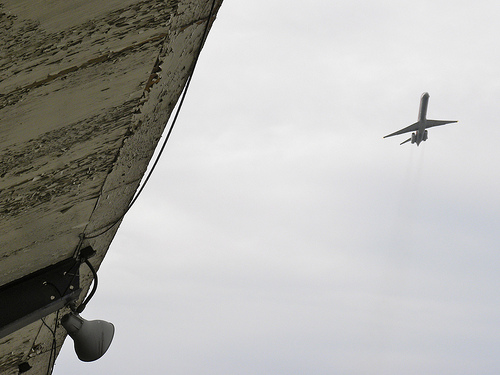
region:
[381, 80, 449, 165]
plane in flight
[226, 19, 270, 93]
white clouds against blue sky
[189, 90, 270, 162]
white clouds against blue sky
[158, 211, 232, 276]
white clouds against blue sky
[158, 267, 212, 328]
white clouds against blue sky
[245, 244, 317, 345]
white clouds against blue sky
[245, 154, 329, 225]
white clouds against blue sky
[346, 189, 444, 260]
white clouds against blue sky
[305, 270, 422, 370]
white clouds against blue sky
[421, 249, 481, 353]
white clouds against blue sky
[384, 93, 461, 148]
The plane flying vertically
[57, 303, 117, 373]
The gray lighting on the wall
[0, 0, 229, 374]
The old gray paint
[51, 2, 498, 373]
The gray open sky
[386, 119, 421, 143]
The gray wing on the left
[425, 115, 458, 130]
The gray wing on the right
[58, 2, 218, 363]
The black cable on the wall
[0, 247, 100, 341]
The dark roofing bar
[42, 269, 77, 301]
The bar with four holes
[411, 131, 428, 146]
The rear plane engines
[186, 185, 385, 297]
Sky is white color.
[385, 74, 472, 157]
Plane is flying in air.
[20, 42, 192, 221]
part of boat is seen in let side.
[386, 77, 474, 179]
plane is white color.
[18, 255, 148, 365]
light is attached to the boat.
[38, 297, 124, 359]
Light is white color.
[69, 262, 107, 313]
Wire is black color.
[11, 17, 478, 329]
Day time picture.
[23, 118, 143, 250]
Boat is grey color.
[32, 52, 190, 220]
boat is made of wood.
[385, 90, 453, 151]
The jet is in the air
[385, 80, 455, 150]
The jet is white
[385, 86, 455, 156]
The jet is flying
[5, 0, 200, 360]
Post attached to the wall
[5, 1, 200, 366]
The paint is peeling off the wall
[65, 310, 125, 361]
The wall is tall and white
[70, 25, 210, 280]
The wire is black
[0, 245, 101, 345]
The post is black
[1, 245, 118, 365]
The light is attached to the post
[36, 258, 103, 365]
Multiple wires attached to the light and post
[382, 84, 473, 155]
airplane in flight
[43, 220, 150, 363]
light and power supply under ledge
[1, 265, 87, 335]
metal beam under roof ledge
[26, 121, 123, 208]
chipped and pealing paint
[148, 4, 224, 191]
edge of a roof with wire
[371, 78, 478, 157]
a comercial aircraft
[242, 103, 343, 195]
a clear sky with no clouds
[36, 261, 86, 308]
four holes drilled into metal beam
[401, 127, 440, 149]
airplane jet engines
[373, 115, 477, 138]
wings of an airplane